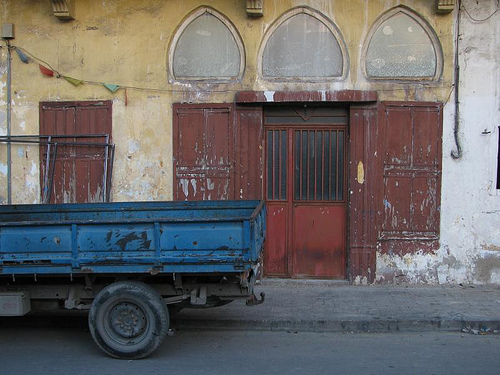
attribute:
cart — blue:
[33, 202, 254, 323]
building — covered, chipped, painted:
[63, 47, 464, 276]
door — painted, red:
[233, 123, 386, 294]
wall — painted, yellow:
[21, 38, 162, 104]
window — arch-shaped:
[358, 2, 445, 90]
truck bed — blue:
[3, 200, 273, 273]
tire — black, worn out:
[84, 279, 175, 360]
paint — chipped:
[354, 155, 368, 192]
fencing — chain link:
[7, 135, 114, 195]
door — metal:
[266, 118, 349, 288]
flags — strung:
[6, 40, 131, 97]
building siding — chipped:
[10, 87, 169, 189]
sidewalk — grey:
[198, 283, 498, 330]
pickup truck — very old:
[0, 193, 276, 359]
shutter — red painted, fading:
[368, 95, 443, 255]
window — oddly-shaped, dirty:
[258, 2, 347, 82]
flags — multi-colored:
[13, 31, 124, 101]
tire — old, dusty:
[89, 277, 172, 367]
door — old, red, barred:
[266, 110, 344, 278]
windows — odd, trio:
[164, 7, 445, 86]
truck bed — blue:
[0, 192, 272, 279]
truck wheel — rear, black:
[87, 278, 171, 363]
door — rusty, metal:
[263, 118, 348, 273]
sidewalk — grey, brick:
[170, 280, 496, 326]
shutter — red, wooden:
[380, 100, 443, 240]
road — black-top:
[0, 333, 493, 373]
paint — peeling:
[250, 85, 375, 125]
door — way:
[247, 73, 383, 119]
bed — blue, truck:
[25, 192, 266, 268]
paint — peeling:
[370, 238, 484, 286]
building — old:
[2, 0, 484, 290]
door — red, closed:
[233, 83, 383, 286]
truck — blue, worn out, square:
[0, 197, 275, 363]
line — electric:
[11, 39, 459, 95]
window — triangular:
[168, 5, 245, 81]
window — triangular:
[260, 11, 341, 84]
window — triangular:
[363, 8, 439, 78]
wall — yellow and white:
[0, 0, 500, 286]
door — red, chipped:
[253, 104, 348, 280]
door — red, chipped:
[358, 98, 442, 286]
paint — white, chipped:
[0, 0, 498, 286]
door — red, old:
[264, 103, 346, 281]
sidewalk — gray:
[0, 276, 500, 333]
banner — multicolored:
[2, 35, 242, 95]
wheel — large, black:
[83, 278, 173, 358]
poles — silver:
[1, 130, 119, 204]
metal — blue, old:
[1, 199, 270, 279]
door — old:
[369, 99, 442, 279]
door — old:
[171, 100, 246, 203]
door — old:
[36, 96, 112, 204]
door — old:
[372, 98, 447, 283]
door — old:
[171, 99, 242, 208]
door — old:
[265, 99, 352, 276]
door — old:
[369, 98, 439, 259]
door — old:
[171, 100, 237, 200]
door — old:
[40, 96, 113, 199]